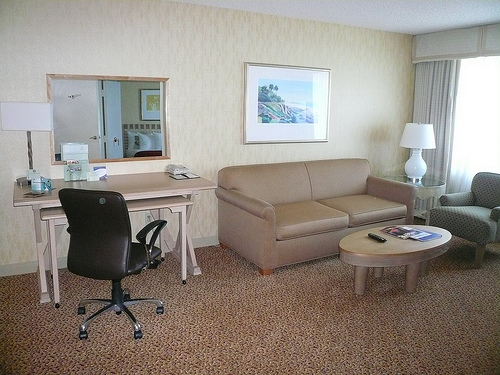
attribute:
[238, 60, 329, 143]
artwork — framed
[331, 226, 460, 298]
table — wooden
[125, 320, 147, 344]
black wheel — shiny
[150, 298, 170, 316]
black wheel — shiny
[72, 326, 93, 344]
black wheel — shiny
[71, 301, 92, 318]
black wheel — shiny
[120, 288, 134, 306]
black wheel — shiny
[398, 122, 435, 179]
table lamp — white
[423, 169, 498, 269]
chair — accent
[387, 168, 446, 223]
table — round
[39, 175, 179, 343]
chair — black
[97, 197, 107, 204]
circle — tiny, gray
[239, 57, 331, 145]
picture — white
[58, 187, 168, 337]
chair — big, black, large, swivel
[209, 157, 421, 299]
sofa — brown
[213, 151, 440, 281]
leather couch — tan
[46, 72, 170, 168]
mirror — framed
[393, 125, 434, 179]
lamp — white, table lamp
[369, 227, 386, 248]
remote — black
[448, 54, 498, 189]
window — glass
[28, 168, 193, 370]
chair — desk chair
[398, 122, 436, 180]
lamp — white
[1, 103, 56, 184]
lamp — white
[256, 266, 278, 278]
leg — small, brown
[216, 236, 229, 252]
leg — small, brown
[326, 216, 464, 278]
table — oval, coffee table